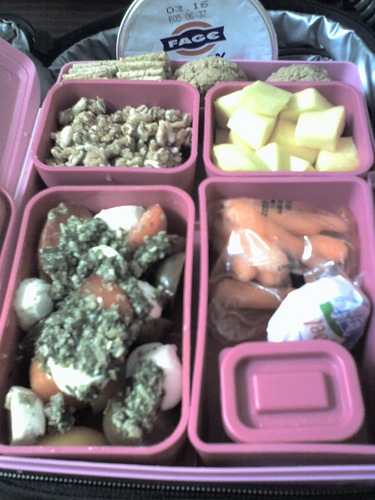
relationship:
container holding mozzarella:
[201, 82, 374, 178] [94, 205, 152, 240]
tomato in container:
[30, 360, 58, 402] [1, 184, 196, 457]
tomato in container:
[82, 278, 137, 312] [1, 184, 196, 457]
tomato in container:
[128, 205, 174, 252] [1, 184, 196, 457]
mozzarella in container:
[94, 205, 152, 240] [1, 184, 196, 457]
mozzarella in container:
[15, 277, 55, 329] [1, 184, 196, 457]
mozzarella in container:
[127, 342, 179, 410] [1, 184, 196, 457]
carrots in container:
[210, 199, 360, 310] [186, 175, 374, 469]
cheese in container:
[266, 275, 372, 352] [186, 175, 374, 469]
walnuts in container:
[45, 98, 192, 169] [31, 80, 202, 188]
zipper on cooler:
[1, 470, 374, 499] [0, 3, 373, 500]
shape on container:
[251, 371, 334, 416] [220, 342, 370, 443]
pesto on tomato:
[34, 293, 123, 374] [82, 278, 137, 312]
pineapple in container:
[214, 79, 361, 172] [201, 82, 374, 178]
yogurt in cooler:
[116, 1, 278, 61] [0, 3, 373, 500]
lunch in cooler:
[1, 0, 370, 446] [0, 3, 373, 500]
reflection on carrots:
[226, 225, 315, 270] [210, 199, 360, 310]